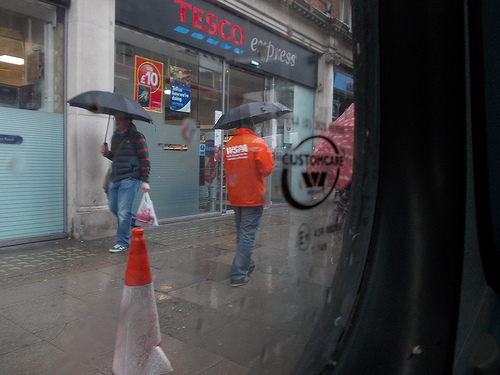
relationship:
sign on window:
[134, 56, 164, 114] [116, 23, 223, 222]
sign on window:
[169, 65, 191, 113] [116, 23, 223, 222]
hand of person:
[140, 180, 150, 194] [98, 112, 150, 254]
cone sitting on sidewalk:
[109, 226, 169, 375] [1, 204, 338, 375]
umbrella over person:
[213, 101, 293, 130] [218, 121, 273, 287]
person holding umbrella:
[98, 112, 150, 254] [66, 90, 155, 125]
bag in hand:
[134, 189, 159, 230] [140, 180, 150, 194]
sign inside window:
[134, 56, 164, 114] [116, 23, 223, 222]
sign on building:
[134, 56, 164, 114] [1, 0, 355, 249]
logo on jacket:
[224, 144, 251, 162] [221, 129, 273, 208]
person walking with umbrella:
[98, 112, 150, 254] [66, 90, 155, 125]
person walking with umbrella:
[218, 121, 273, 287] [213, 101, 293, 130]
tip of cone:
[131, 228, 144, 236] [109, 226, 169, 375]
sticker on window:
[279, 135, 346, 212] [1, 2, 381, 374]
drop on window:
[324, 286, 335, 303] [1, 2, 381, 374]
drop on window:
[334, 314, 343, 325] [1, 2, 381, 374]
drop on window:
[356, 42, 361, 56] [1, 2, 381, 374]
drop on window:
[347, 252, 351, 265] [1, 2, 381, 374]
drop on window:
[199, 313, 208, 335] [1, 2, 381, 374]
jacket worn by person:
[221, 129, 273, 208] [218, 121, 273, 287]